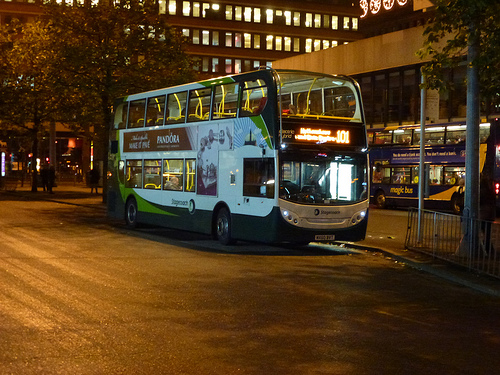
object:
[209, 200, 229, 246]
wheel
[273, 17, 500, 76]
wall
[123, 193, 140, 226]
back wheel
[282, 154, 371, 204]
windshield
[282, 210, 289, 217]
headlight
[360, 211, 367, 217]
headlight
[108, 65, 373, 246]
bus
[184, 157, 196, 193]
window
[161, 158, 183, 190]
window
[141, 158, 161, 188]
window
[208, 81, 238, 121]
window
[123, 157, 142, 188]
window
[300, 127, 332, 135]
letters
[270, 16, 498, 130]
bluilding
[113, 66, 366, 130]
top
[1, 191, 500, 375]
road